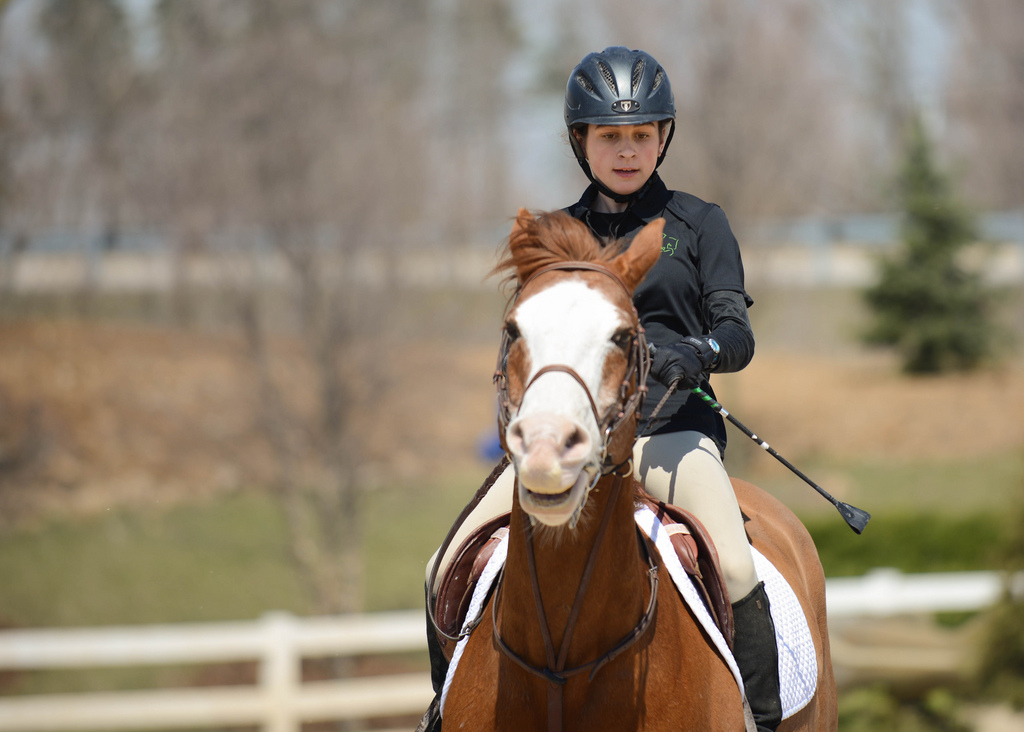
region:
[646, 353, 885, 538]
black leather riding crop in the ladies hand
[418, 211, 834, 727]
white and brown horse in the field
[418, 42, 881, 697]
girl on the back of the brown and white horse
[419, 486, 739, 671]
brown and leather saddle on the horse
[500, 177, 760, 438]
black shirt on the girl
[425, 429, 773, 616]
tan pants on the girl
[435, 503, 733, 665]
brown and leather saddle under the girl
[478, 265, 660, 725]
brown leather harness on the horse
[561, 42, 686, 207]
a black riding helmet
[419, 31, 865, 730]
woman wearing a black riding helmet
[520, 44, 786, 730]
woman in a black jacket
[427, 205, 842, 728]
brown and white horse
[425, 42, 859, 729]
woman riding a horse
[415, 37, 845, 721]
woman riding a brown and white horse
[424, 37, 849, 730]
woman sitting on a horse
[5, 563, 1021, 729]
a white wooden fence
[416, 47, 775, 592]
woman wearing tan pants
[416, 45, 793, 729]
woman wearing black riding boots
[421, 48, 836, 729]
the girl riding on the horse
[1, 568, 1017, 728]
the fence is white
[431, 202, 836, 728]
the horse is brown and white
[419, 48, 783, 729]
the girl is wearing a black helmet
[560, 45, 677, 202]
the helmet has a strap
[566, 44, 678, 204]
the helmet is black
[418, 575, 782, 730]
the boots are black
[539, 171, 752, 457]
the shirt is black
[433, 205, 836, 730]
the saddle on the horse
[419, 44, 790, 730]
person riding a horse in protective gear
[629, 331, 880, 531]
black riding crop held in left hand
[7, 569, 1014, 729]
white fence in the background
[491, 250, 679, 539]
brown leather bridal for controlling the horse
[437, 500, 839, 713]
white blanket under the saddle to protect the horse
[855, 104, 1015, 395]
out of focus green pine tree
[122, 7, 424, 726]
tree without any leaves on it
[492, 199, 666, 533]
horse face with large white blaze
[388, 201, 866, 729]
a horse is white and brown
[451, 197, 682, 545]
horse has white face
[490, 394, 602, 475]
the nostrils are white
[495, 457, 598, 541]
the white mouth is open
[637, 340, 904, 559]
a pole on a hand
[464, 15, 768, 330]
woman wearing black helmet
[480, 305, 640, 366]
two eyes of a horse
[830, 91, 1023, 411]
the tree is green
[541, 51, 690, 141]
The woman is wearing a black helmet.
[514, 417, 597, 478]
The nose on the horse.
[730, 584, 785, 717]
The riding boots are black.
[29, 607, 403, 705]
The fence is white.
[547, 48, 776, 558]
A woman on top of the horse.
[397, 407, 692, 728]
The horse is brown.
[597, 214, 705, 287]
The horse has big ear.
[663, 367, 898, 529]
The woman is holding the stick.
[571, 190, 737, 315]
The shirt is black.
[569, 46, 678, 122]
the helmet is black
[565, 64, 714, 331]
a person in a black helmet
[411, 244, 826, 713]
a brown and white horse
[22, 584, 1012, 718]
a white fence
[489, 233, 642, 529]
the face of the horse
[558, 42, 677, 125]
The black helmet on the head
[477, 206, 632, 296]
The mane on the horse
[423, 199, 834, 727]
The horse is brown